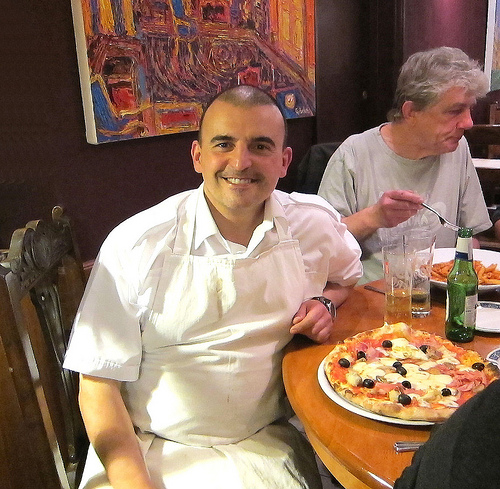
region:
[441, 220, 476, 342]
empty beer bottle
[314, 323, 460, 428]
part of a pizza on a plate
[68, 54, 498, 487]
two men sitting on a dinner table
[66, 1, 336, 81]
part of a wall painting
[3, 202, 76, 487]
back of a dining chair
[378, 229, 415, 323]
tall glass with beer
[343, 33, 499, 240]
a man holding a fork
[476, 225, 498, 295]
pasta in a plate in red souce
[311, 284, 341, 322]
a man's watch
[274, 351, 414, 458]
the top of a dining table with a plate of pizza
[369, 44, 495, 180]
The man has hair.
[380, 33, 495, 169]
The man's hair is gray.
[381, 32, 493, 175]
The man's hair is wavy.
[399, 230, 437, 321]
The glass is clear.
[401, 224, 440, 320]
The glass is almost empty.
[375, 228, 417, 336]
The glass is clear.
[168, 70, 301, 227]
The man is smiling.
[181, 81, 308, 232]
The man's haed is shaved.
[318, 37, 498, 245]
The man is holding a fork.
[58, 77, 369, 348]
The man is wearing a watch.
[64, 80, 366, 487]
a man in an apron sitting down at the table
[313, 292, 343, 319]
a man's wrist watch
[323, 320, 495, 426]
a tasty looking pizza pie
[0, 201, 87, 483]
an intricately carved chair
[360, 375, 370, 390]
a whole black olive on a pizza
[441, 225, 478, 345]
an empty beer bottle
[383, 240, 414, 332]
a half filled glass of beer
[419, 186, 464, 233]
a fork in a man's hand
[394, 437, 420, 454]
a handle of service utensil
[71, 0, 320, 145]
a colorful painting on the wall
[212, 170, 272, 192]
wide grin on man's face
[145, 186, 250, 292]
apron strings around neck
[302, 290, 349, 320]
bulky silver watch on hand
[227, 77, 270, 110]
bald spot on man's head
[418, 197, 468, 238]
silver spoon in man's hand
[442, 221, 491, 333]
tall green and white wine bottle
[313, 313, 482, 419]
large white plate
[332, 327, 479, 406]
pizza pie on plate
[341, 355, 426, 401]
large black olives on pie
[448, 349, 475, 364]
slices of yellow banana peppers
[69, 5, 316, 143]
A painting on a wall.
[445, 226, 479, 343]
A bottle on a table.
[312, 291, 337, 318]
A watch on a wrist.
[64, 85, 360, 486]
A man in a white shirt.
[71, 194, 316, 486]
A white apron.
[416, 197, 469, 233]
A folk.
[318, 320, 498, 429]
A food on a plate.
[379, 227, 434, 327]
Two glasses on a table.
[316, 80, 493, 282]
A man in a t-shirt.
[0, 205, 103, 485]
A back of a chair.